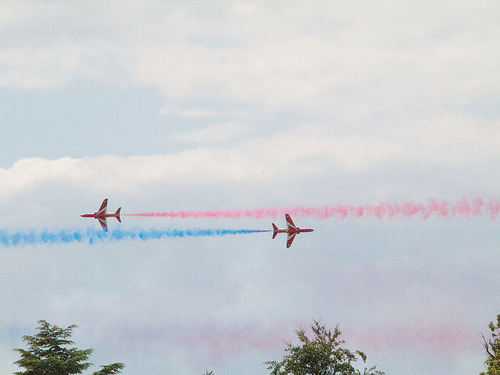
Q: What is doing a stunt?
A: Two planes.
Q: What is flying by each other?
A: The planes.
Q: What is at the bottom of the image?
A: The trees.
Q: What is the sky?
A: Cloudy.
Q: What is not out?
A: The sun.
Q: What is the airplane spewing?
A: Pink smoke.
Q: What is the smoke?
A: Pink.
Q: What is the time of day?
A: It is Daytime.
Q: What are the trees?
A: Tall.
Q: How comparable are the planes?
A: They are similar in shape and color.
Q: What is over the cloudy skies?
A: The aircrafts releasing pink and blue jet streams on their respective ways.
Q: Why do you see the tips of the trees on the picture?
A: Because the trees are tall.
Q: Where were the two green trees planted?
A: Next to each other.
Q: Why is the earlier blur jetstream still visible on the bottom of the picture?
A: Because it contrasts from the white cloud background.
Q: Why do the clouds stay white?
A: Because the clouds are thick.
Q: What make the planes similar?
A: The colors and shape.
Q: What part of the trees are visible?
A: Tops.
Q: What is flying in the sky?
A: Planes.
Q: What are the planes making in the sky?
A: Colorful lines.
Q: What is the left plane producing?
A: Red smoke.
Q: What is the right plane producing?
A: Blue smoke.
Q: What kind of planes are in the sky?
A: Jets.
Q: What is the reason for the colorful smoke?
A: Air show.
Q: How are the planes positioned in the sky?
A: Sideways.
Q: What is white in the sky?
A: Clouds.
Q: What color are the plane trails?
A: Blue and pink.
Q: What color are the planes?
A: Red and white.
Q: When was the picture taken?
A: Daytime.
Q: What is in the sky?
A: Planes.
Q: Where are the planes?
A: In the sky.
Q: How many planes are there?
A: Two.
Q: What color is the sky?
A: Blue.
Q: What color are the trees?
A: Green.